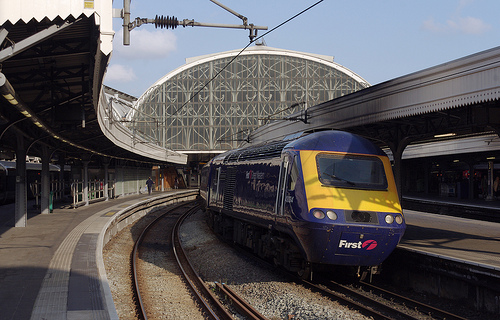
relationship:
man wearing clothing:
[140, 174, 157, 201] [146, 177, 153, 189]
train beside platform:
[195, 128, 407, 282] [1, 186, 200, 316]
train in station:
[195, 128, 407, 282] [400, 174, 494, 261]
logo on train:
[333, 233, 380, 259] [191, 121, 413, 291]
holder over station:
[116, 2, 277, 49] [1, 9, 484, 316]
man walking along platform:
[145, 177, 155, 196] [46, 194, 138, 266]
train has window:
[191, 121, 413, 291] [314, 151, 389, 191]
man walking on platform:
[145, 177, 155, 196] [1, 186, 200, 316]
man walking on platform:
[145, 177, 155, 196] [1, 183, 183, 318]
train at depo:
[195, 128, 407, 282] [338, 71, 451, 189]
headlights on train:
[278, 123, 403, 269] [179, 129, 419, 287]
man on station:
[145, 177, 155, 196] [385, 53, 440, 195]